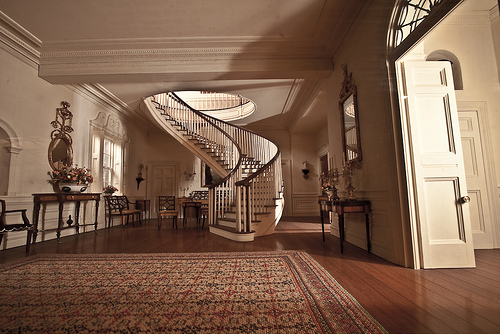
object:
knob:
[455, 188, 473, 208]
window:
[88, 125, 128, 191]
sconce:
[288, 142, 340, 207]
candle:
[295, 157, 312, 173]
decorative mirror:
[55, 81, 352, 176]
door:
[404, 51, 490, 276]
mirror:
[336, 68, 365, 168]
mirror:
[35, 113, 87, 190]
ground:
[289, 70, 321, 141]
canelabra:
[317, 179, 342, 204]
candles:
[314, 161, 339, 177]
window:
[94, 138, 120, 193]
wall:
[1, 31, 147, 251]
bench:
[103, 193, 141, 226]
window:
[90, 135, 125, 193]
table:
[26, 188, 115, 240]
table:
[310, 190, 375, 265]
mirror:
[339, 77, 366, 166]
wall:
[216, 86, 246, 173]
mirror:
[327, 62, 375, 175]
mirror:
[23, 102, 102, 194]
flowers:
[49, 159, 101, 185]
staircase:
[121, 53, 301, 247]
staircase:
[156, 91, 278, 231]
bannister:
[183, 95, 280, 185]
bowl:
[52, 182, 99, 192]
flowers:
[53, 162, 92, 181]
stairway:
[139, 88, 289, 243]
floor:
[1, 217, 499, 332]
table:
[318, 197, 375, 255]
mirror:
[328, 65, 372, 167]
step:
[207, 222, 255, 240]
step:
[217, 215, 244, 229]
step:
[222, 208, 267, 220]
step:
[230, 202, 278, 210]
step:
[231, 197, 281, 205]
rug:
[0, 245, 389, 332]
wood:
[54, 191, 78, 202]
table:
[34, 190, 102, 235]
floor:
[348, 273, 494, 332]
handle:
[458, 191, 469, 206]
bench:
[103, 186, 132, 221]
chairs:
[103, 191, 141, 223]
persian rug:
[5, 249, 385, 332]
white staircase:
[151, 91, 287, 239]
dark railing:
[168, 90, 278, 185]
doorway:
[385, 9, 498, 271]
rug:
[78, 240, 287, 314]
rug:
[3, 255, 393, 330]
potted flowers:
[53, 164, 93, 184]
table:
[33, 186, 110, 218]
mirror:
[49, 135, 71, 174]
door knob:
[451, 188, 477, 209]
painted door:
[379, 54, 478, 269]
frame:
[46, 99, 74, 172]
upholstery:
[104, 207, 142, 221]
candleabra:
[316, 165, 339, 200]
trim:
[168, 94, 282, 194]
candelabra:
[340, 154, 357, 203]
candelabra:
[322, 163, 338, 202]